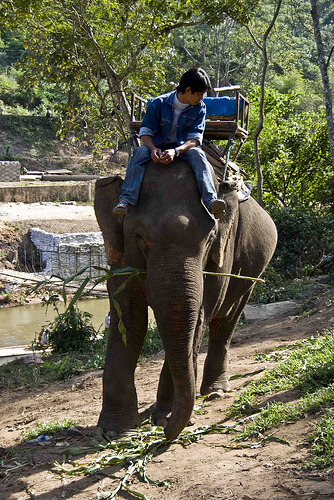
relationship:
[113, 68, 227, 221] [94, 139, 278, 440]
man on elephant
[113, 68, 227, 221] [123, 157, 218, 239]
man on head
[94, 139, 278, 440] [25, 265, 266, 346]
elephant with stalk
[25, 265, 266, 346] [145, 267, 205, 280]
stalk in mouth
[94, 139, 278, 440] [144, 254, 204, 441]
elephant has trunk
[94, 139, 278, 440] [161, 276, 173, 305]
elephant trunk grey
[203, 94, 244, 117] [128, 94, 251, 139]
blanket on seat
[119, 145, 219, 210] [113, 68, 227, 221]
jeans on man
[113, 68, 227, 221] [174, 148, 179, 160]
boy with watch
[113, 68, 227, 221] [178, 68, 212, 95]
boy with hair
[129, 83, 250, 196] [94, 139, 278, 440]
seat on elephant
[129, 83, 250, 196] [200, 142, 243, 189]
seat on back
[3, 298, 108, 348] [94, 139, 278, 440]
water near elephant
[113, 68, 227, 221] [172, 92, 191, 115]
man with turtleneck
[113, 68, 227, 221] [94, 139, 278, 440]
guy on elephant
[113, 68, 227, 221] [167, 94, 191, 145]
boy with shirt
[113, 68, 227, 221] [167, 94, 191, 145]
boy has shirt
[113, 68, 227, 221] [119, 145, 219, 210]
boy with pants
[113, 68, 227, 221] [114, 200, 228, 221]
boy has shoes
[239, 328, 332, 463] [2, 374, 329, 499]
grass on ground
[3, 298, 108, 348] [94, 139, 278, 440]
water behind elephant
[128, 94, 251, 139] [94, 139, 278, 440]
seat on elephant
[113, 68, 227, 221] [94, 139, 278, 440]
boy on elephant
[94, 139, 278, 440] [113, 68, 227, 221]
elephant carries man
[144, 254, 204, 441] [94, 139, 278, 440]
trunk of elephant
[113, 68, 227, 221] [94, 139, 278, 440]
man sits elephant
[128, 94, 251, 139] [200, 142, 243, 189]
bench on back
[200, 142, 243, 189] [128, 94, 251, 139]
back has bench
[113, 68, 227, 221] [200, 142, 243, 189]
man on back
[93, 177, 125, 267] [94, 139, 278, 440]
ear of elephant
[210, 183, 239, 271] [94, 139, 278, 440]
ear of elephant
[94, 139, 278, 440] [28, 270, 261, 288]
elephant has stick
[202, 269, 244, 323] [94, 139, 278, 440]
belly of elephant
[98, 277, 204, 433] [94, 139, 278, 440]
legs of elephant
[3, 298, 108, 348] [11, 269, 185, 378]
river with water